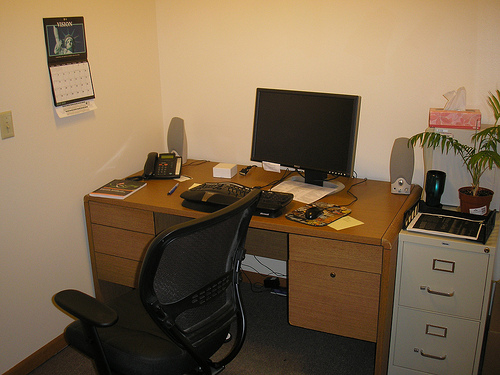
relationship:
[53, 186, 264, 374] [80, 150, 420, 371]
black chair in front of desk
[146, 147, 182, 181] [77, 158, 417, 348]
phone on desk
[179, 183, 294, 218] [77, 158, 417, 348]
keyboard on desk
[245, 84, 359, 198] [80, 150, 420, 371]
monitor on desk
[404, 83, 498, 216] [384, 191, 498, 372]
plant on filing cabinet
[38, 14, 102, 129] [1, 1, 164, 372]
calendar on wall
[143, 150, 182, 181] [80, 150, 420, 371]
phone on desk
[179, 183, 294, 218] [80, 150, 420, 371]
keyboard on desk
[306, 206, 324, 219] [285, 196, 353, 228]
mouse on mousepad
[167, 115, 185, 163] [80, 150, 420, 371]
speaker on desk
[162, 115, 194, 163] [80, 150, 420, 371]
speaker on desk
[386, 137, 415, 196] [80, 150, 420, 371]
speaker on desk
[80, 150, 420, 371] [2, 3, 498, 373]
desk in office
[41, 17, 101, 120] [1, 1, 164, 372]
calendar on wall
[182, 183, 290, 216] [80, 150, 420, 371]
keyboard on desk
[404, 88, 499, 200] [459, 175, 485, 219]
plant in brown pot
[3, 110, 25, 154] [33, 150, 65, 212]
switch plate on wall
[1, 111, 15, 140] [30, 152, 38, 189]
light switch on wall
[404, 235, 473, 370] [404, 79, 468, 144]
file cabinet next to wall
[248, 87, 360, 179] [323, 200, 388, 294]
monitor on desk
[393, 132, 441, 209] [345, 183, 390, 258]
speaker on desk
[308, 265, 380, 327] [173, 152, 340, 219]
lock on desk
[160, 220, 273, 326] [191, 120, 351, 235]
black chair by desk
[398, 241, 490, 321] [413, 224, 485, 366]
file cabinet by desk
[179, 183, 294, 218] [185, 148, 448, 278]
keyboard on desk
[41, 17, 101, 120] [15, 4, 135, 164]
calendar on wall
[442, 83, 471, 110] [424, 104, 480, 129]
tissues in box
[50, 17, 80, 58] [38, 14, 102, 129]
picture on calendar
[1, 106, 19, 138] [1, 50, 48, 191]
light switch on wall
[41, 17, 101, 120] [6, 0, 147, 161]
calendar on wall